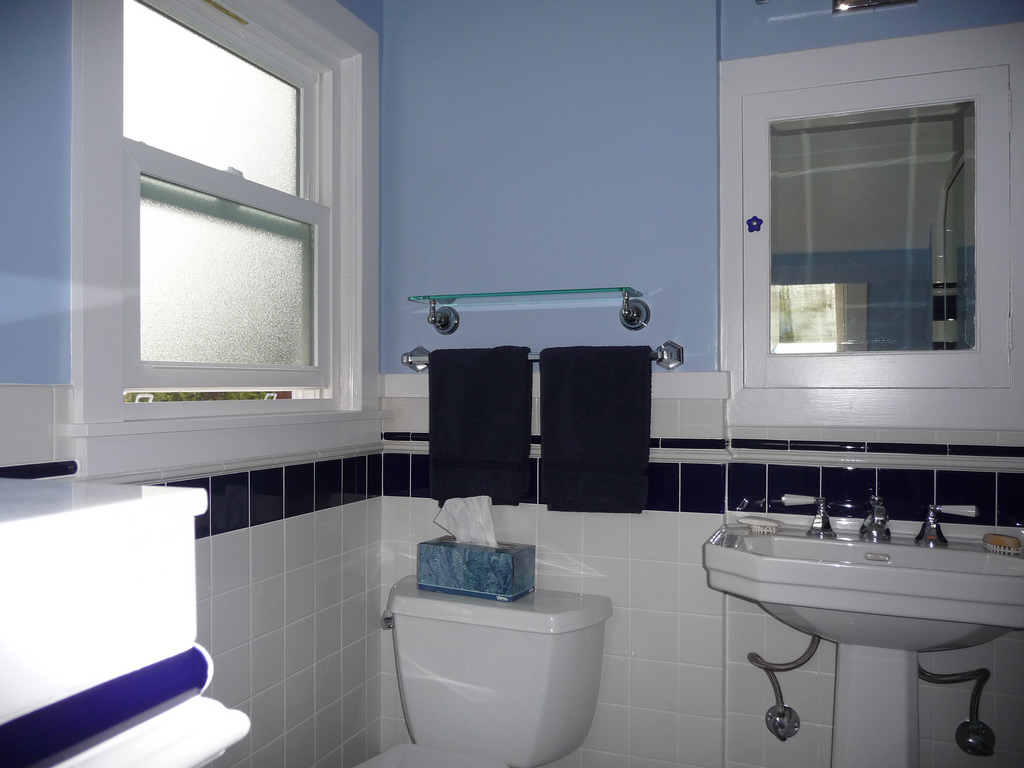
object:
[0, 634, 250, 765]
bar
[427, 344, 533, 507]
towel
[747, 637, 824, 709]
pipe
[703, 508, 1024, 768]
sinj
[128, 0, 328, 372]
window